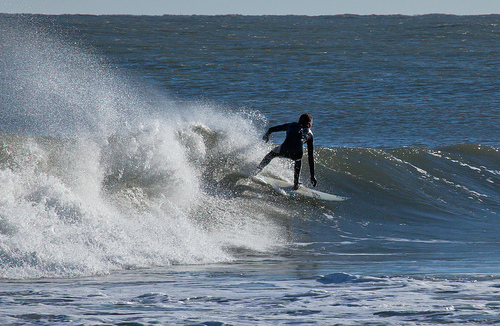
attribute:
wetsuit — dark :
[269, 122, 316, 172]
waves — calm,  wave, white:
[3, 126, 500, 272]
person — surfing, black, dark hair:
[252, 114, 320, 191]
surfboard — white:
[268, 180, 352, 204]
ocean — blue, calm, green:
[1, 16, 499, 325]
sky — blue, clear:
[0, 0, 500, 15]